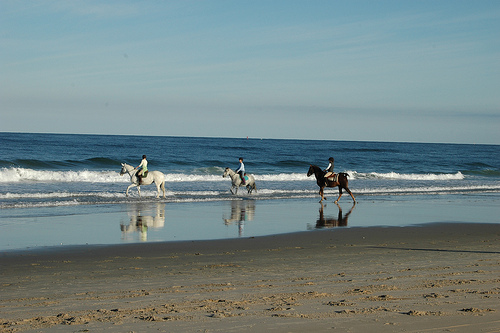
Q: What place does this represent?
A: It represents the beach.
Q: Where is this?
A: This is at the beach.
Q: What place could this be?
A: It is a beach.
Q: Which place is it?
A: It is a beach.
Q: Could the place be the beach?
A: Yes, it is the beach.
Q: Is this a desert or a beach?
A: It is a beach.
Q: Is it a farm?
A: No, it is a beach.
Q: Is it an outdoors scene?
A: Yes, it is outdoors.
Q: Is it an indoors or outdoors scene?
A: It is outdoors.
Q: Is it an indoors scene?
A: No, it is outdoors.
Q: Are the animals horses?
A: Yes, all the animals are horses.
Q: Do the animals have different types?
A: No, all the animals are horses.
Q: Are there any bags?
A: No, there are no bags.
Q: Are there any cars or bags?
A: No, there are no bags or cars.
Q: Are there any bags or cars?
A: No, there are no bags or cars.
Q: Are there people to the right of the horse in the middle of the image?
A: Yes, there is a person to the right of the horse.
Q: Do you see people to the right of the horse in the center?
A: Yes, there is a person to the right of the horse.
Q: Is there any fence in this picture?
A: No, there are no fences.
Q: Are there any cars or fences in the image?
A: No, there are no fences or cars.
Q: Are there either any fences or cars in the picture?
A: No, there are no fences or cars.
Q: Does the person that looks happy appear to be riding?
A: Yes, the person is riding.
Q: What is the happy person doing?
A: The person is riding.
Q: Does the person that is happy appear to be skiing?
A: No, the person is riding.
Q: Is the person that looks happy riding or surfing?
A: The person is riding.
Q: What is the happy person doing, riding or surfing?
A: The person is riding.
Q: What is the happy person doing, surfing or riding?
A: The person is riding.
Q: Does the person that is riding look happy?
A: Yes, the person is happy.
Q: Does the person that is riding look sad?
A: No, the person is happy.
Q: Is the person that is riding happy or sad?
A: The person is happy.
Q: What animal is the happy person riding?
A: The person is riding a horse.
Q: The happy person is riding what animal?
A: The person is riding a horse.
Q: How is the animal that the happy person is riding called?
A: The animal is a horse.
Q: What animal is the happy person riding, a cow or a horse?
A: The person is riding a horse.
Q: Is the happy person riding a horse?
A: Yes, the person is riding a horse.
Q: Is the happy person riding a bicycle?
A: No, the person is riding a horse.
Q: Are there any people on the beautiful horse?
A: Yes, there is a person on the horse.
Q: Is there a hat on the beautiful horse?
A: No, there is a person on the horse.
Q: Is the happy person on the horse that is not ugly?
A: Yes, the person is on the horse.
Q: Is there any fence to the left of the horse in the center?
A: No, there is a person to the left of the horse.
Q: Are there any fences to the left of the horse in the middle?
A: No, there is a person to the left of the horse.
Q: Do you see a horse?
A: Yes, there is a horse.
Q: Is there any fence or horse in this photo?
A: Yes, there is a horse.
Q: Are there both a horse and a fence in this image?
A: No, there is a horse but no fences.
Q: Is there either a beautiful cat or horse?
A: Yes, there is a beautiful horse.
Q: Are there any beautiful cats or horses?
A: Yes, there is a beautiful horse.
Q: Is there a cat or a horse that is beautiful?
A: Yes, the horse is beautiful.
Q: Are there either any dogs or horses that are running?
A: Yes, the horse is running.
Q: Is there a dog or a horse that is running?
A: Yes, the horse is running.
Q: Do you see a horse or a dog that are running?
A: Yes, the horse is running.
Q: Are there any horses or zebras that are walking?
A: Yes, the horse is walking.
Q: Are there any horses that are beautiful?
A: Yes, there is a beautiful horse.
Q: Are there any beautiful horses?
A: Yes, there is a beautiful horse.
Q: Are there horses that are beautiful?
A: Yes, there is a horse that is beautiful.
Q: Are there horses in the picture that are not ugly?
A: Yes, there is an beautiful horse.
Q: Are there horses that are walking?
A: Yes, there is a horse that is walking.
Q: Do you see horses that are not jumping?
A: Yes, there is a horse that is walking .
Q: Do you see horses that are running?
A: Yes, there is a horse that is running.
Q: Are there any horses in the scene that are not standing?
A: Yes, there is a horse that is running.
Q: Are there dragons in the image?
A: No, there are no dragons.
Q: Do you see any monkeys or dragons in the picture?
A: No, there are no dragons or monkeys.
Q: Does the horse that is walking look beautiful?
A: Yes, the horse is beautiful.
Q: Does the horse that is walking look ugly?
A: No, the horse is beautiful.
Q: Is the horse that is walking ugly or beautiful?
A: The horse is beautiful.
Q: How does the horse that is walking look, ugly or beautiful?
A: The horse is beautiful.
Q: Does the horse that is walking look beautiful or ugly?
A: The horse is beautiful.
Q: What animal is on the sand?
A: The animal is a horse.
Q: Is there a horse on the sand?
A: Yes, there is a horse on the sand.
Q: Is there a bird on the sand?
A: No, there is a horse on the sand.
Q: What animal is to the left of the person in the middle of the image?
A: The animal is a horse.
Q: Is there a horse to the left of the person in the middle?
A: Yes, there is a horse to the left of the person.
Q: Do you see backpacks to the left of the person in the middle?
A: No, there is a horse to the left of the person.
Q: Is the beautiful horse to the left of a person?
A: Yes, the horse is to the left of a person.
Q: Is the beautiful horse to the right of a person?
A: No, the horse is to the left of a person.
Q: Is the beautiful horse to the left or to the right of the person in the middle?
A: The horse is to the left of the person.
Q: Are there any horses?
A: Yes, there is a horse.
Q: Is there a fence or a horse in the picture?
A: Yes, there is a horse.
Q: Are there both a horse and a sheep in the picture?
A: No, there is a horse but no sheep.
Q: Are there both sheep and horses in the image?
A: No, there is a horse but no sheep.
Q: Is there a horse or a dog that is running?
A: Yes, the horse is running.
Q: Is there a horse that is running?
A: Yes, there is a horse that is running.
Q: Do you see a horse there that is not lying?
A: Yes, there is a horse that is running .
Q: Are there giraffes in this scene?
A: No, there are no giraffes.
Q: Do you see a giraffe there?
A: No, there are no giraffes.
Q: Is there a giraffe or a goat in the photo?
A: No, there are no giraffes or goats.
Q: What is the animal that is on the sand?
A: The animal is a horse.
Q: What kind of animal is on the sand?
A: The animal is a horse.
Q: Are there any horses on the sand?
A: Yes, there is a horse on the sand.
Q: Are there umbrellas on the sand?
A: No, there is a horse on the sand.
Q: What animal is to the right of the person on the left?
A: The animal is a horse.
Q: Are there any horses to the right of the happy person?
A: Yes, there is a horse to the right of the person.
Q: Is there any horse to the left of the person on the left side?
A: No, the horse is to the right of the person.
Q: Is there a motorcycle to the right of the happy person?
A: No, there is a horse to the right of the person.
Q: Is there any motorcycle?
A: No, there are no motorcycles.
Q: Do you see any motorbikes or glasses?
A: No, there are no motorbikes or glasses.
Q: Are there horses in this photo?
A: Yes, there is a horse.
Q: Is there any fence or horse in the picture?
A: Yes, there is a horse.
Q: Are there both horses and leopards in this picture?
A: No, there is a horse but no leopards.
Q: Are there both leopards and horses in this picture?
A: No, there is a horse but no leopards.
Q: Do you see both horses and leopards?
A: No, there is a horse but no leopards.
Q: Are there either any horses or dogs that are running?
A: Yes, the horse is running.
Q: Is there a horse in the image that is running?
A: Yes, there is a horse that is running.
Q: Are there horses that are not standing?
A: Yes, there is a horse that is running.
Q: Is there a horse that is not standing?
A: Yes, there is a horse that is running.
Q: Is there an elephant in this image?
A: No, there are no elephants.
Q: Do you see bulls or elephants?
A: No, there are no elephants or bulls.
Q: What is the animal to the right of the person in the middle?
A: The animal is a horse.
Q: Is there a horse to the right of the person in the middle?
A: Yes, there is a horse to the right of the person.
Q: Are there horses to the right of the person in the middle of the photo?
A: Yes, there is a horse to the right of the person.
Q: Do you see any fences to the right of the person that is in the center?
A: No, there is a horse to the right of the person.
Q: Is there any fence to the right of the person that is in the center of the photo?
A: No, there is a horse to the right of the person.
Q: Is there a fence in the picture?
A: No, there are no fences.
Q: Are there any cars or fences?
A: No, there are no fences or cars.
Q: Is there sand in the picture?
A: Yes, there is sand.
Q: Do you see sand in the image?
A: Yes, there is sand.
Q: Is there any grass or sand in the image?
A: Yes, there is sand.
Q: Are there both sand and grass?
A: No, there is sand but no grass.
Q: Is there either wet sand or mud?
A: Yes, there is wet sand.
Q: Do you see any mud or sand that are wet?
A: Yes, the sand is wet.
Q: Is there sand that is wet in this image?
A: Yes, there is wet sand.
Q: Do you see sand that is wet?
A: Yes, there is sand that is wet.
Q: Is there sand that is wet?
A: Yes, there is sand that is wet.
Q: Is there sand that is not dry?
A: Yes, there is wet sand.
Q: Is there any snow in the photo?
A: No, there is no snow.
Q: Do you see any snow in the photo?
A: No, there is no snow.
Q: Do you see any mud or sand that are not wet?
A: No, there is sand but it is wet.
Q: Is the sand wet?
A: Yes, the sand is wet.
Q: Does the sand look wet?
A: Yes, the sand is wet.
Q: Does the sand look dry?
A: No, the sand is wet.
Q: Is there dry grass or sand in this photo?
A: No, there is sand but it is wet.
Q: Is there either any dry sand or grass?
A: No, there is sand but it is wet.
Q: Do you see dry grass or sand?
A: No, there is sand but it is wet.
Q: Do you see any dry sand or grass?
A: No, there is sand but it is wet.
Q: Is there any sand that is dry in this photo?
A: No, there is sand but it is wet.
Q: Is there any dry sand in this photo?
A: No, there is sand but it is wet.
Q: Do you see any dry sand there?
A: No, there is sand but it is wet.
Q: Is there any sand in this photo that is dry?
A: No, there is sand but it is wet.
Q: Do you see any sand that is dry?
A: No, there is sand but it is wet.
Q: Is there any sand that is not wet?
A: No, there is sand but it is wet.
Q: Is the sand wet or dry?
A: The sand is wet.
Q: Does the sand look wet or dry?
A: The sand is wet.